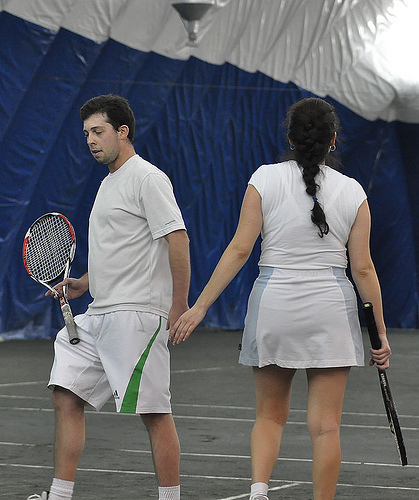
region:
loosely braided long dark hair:
[285, 95, 337, 241]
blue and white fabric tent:
[0, 1, 417, 341]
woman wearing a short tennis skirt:
[166, 93, 392, 498]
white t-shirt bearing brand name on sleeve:
[82, 152, 187, 320]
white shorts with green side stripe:
[43, 306, 174, 414]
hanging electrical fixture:
[163, 1, 227, 47]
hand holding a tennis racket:
[20, 211, 84, 346]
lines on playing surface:
[1, 348, 417, 498]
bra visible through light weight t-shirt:
[246, 158, 368, 271]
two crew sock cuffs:
[46, 475, 181, 498]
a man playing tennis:
[32, 102, 206, 443]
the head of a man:
[66, 93, 137, 173]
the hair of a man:
[84, 77, 118, 118]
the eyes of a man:
[85, 120, 101, 146]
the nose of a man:
[76, 134, 110, 146]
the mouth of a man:
[76, 145, 120, 162]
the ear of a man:
[109, 120, 130, 139]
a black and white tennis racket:
[19, 208, 89, 361]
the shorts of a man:
[33, 311, 176, 420]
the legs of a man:
[57, 388, 184, 495]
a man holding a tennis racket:
[28, 90, 200, 497]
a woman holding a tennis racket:
[160, 90, 408, 498]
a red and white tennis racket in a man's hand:
[20, 201, 88, 350]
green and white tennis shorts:
[45, 298, 179, 420]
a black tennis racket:
[354, 298, 413, 476]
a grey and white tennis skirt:
[240, 251, 368, 378]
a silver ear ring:
[328, 141, 339, 156]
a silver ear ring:
[288, 138, 297, 154]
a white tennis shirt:
[78, 154, 192, 325]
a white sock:
[47, 469, 84, 498]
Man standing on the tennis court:
[23, 93, 188, 499]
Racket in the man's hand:
[21, 212, 80, 345]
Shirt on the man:
[84, 153, 186, 315]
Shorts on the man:
[46, 310, 171, 415]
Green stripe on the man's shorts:
[119, 314, 163, 415]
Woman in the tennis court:
[167, 96, 409, 499]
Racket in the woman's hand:
[361, 301, 408, 467]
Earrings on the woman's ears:
[288, 141, 335, 151]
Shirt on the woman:
[246, 161, 367, 268]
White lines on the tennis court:
[0, 365, 416, 499]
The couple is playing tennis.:
[26, 96, 392, 498]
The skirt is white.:
[271, 277, 329, 347]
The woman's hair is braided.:
[301, 111, 328, 236]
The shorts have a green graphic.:
[122, 392, 137, 412]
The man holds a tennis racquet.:
[20, 210, 82, 344]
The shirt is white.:
[98, 208, 149, 292]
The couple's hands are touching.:
[165, 301, 206, 345]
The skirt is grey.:
[243, 325, 256, 359]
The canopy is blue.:
[153, 82, 243, 142]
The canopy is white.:
[257, 8, 352, 58]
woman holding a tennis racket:
[200, 85, 413, 393]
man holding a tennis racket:
[6, 90, 195, 496]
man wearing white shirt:
[28, 90, 189, 483]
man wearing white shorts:
[36, 91, 196, 495]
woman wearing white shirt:
[187, 83, 392, 498]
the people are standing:
[59, 70, 370, 412]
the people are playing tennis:
[16, 37, 401, 433]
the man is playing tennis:
[32, 82, 189, 311]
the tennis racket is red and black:
[22, 198, 120, 348]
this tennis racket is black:
[346, 310, 412, 421]